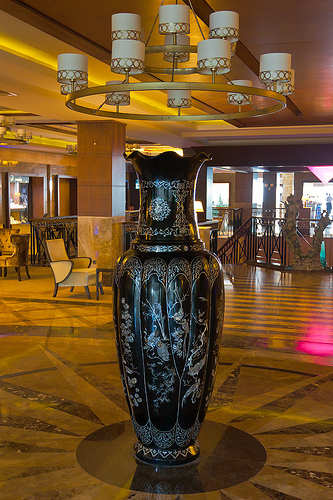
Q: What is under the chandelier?
A: A vase.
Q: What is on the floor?
A: A pink light.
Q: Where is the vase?
A: In the middle of the floor.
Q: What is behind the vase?
A: A staircase.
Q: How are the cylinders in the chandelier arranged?
A: In a circular pattern.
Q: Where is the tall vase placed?
A: On the floor.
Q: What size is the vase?
A: Long and narrow.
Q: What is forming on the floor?
A: Long bright shadows.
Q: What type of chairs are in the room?
A: White armchairs.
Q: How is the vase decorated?
A: In Chinese patterns.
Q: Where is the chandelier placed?
A: On the ceiling.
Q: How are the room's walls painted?
A: In brown paint.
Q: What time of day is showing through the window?
A: Light and sunny.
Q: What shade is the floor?
A: Yellow.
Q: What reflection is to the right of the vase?
A: Pink light.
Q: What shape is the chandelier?
A: Round.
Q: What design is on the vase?
A: Flowers, birds and vines.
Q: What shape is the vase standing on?
A: Circle.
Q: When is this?
A: Daytime.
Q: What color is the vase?
A: Black.